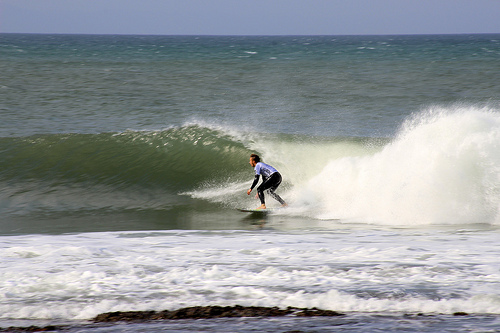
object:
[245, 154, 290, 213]
surfer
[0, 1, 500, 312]
ocean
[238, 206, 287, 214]
board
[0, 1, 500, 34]
sky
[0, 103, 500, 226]
wave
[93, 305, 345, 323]
rock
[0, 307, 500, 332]
beach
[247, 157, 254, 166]
face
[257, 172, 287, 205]
pants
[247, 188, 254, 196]
hand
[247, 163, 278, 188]
shirt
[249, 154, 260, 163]
hair